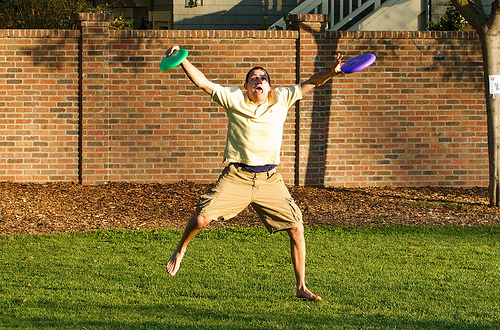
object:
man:
[164, 45, 344, 302]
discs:
[159, 49, 189, 71]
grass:
[0, 224, 497, 328]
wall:
[0, 28, 499, 187]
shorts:
[195, 163, 304, 235]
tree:
[447, 0, 499, 208]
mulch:
[0, 181, 500, 233]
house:
[131, 0, 498, 32]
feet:
[165, 246, 186, 277]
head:
[239, 65, 274, 102]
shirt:
[210, 83, 303, 166]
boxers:
[234, 163, 277, 173]